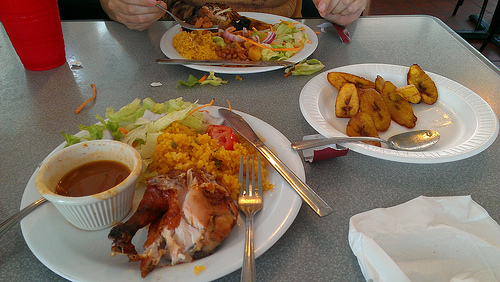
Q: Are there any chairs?
A: No, there are no chairs.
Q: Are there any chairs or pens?
A: No, there are no chairs or pens.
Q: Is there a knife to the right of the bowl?
A: Yes, there are knives to the right of the bowl.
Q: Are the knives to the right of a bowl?
A: Yes, the knives are to the right of a bowl.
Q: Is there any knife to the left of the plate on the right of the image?
A: Yes, there are knives to the left of the plate.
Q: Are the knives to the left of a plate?
A: Yes, the knives are to the left of a plate.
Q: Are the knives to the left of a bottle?
A: No, the knives are to the left of a plate.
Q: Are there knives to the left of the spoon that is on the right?
A: Yes, there are knives to the left of the spoon.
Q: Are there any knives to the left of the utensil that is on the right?
A: Yes, there are knives to the left of the spoon.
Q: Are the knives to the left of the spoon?
A: Yes, the knives are to the left of the spoon.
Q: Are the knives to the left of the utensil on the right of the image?
A: Yes, the knives are to the left of the spoon.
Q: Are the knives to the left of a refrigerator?
A: No, the knives are to the left of the spoon.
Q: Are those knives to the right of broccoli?
A: No, the knives are to the right of the lettuce.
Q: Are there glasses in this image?
A: No, there are no glasses.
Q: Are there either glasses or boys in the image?
A: No, there are no glasses or boys.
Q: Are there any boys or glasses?
A: No, there are no glasses or boys.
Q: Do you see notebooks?
A: No, there are no notebooks.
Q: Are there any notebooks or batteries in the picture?
A: No, there are no notebooks or batteries.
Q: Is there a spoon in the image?
A: Yes, there is a spoon.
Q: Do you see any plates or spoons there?
A: Yes, there is a spoon.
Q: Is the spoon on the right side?
A: Yes, the spoon is on the right of the image.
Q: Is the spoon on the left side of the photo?
A: No, the spoon is on the right of the image.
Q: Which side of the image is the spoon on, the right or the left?
A: The spoon is on the right of the image.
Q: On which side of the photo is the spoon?
A: The spoon is on the right of the image.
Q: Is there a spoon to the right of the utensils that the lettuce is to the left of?
A: Yes, there is a spoon to the right of the knives.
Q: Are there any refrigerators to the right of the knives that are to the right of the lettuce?
A: No, there is a spoon to the right of the knives.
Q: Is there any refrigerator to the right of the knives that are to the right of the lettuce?
A: No, there is a spoon to the right of the knives.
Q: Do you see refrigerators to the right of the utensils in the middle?
A: No, there is a spoon to the right of the knives.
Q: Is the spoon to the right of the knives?
A: Yes, the spoon is to the right of the knives.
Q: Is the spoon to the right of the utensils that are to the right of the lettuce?
A: Yes, the spoon is to the right of the knives.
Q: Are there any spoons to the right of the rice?
A: Yes, there is a spoon to the right of the rice.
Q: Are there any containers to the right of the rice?
A: No, there is a spoon to the right of the rice.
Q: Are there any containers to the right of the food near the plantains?
A: No, there is a spoon to the right of the rice.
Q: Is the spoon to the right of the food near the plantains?
A: Yes, the spoon is to the right of the rice.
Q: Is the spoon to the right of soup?
A: No, the spoon is to the right of the rice.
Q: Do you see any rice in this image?
A: Yes, there is rice.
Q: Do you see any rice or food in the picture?
A: Yes, there is rice.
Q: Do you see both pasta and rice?
A: No, there is rice but no pasta.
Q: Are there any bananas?
A: No, there are no bananas.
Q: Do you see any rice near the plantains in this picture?
A: Yes, there is rice near the plantains.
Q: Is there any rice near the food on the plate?
A: Yes, there is rice near the plantains.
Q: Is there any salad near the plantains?
A: No, there is rice near the plantains.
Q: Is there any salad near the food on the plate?
A: No, there is rice near the plantains.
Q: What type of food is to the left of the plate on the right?
A: The food is rice.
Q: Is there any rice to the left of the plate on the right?
A: Yes, there is rice to the left of the plate.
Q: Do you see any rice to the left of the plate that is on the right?
A: Yes, there is rice to the left of the plate.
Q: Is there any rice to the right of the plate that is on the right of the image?
A: No, the rice is to the left of the plate.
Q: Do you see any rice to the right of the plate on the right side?
A: No, the rice is to the left of the plate.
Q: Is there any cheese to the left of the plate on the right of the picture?
A: No, there is rice to the left of the plate.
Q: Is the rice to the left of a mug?
A: No, the rice is to the left of the plate.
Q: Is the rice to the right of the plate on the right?
A: No, the rice is to the left of the plate.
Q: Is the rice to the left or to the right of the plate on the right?
A: The rice is to the left of the plate.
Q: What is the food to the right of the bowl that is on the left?
A: The food is rice.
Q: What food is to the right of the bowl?
A: The food is rice.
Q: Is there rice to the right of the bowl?
A: Yes, there is rice to the right of the bowl.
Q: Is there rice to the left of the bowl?
A: No, the rice is to the right of the bowl.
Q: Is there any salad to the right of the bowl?
A: No, there is rice to the right of the bowl.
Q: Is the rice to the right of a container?
A: No, the rice is to the right of the bowl.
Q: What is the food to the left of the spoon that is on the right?
A: The food is rice.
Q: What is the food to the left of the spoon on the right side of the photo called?
A: The food is rice.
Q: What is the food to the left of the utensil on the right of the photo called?
A: The food is rice.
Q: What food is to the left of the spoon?
A: The food is rice.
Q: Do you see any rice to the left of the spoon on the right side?
A: Yes, there is rice to the left of the spoon.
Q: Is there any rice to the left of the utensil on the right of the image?
A: Yes, there is rice to the left of the spoon.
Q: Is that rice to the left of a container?
A: No, the rice is to the left of the spoon.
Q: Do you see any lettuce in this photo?
A: Yes, there is lettuce.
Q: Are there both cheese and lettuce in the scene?
A: No, there is lettuce but no cheese.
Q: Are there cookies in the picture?
A: No, there are no cookies.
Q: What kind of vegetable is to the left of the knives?
A: The vegetable is lettuce.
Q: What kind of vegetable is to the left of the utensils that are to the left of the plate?
A: The vegetable is lettuce.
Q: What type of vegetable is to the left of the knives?
A: The vegetable is lettuce.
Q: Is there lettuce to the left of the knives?
A: Yes, there is lettuce to the left of the knives.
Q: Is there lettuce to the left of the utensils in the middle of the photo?
A: Yes, there is lettuce to the left of the knives.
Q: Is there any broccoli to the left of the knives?
A: No, there is lettuce to the left of the knives.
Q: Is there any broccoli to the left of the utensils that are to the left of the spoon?
A: No, there is lettuce to the left of the knives.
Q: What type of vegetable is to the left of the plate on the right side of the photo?
A: The vegetable is lettuce.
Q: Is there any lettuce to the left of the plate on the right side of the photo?
A: Yes, there is lettuce to the left of the plate.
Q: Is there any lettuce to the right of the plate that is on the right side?
A: No, the lettuce is to the left of the plate.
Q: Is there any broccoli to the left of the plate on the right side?
A: No, there is lettuce to the left of the plate.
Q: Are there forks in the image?
A: Yes, there is a fork.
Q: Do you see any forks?
A: Yes, there is a fork.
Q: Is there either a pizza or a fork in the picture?
A: Yes, there is a fork.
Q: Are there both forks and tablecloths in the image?
A: No, there is a fork but no tablecloths.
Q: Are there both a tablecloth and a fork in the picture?
A: No, there is a fork but no tablecloths.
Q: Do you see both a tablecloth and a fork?
A: No, there is a fork but no tablecloths.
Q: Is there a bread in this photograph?
A: No, there is no breads.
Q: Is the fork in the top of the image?
A: Yes, the fork is in the top of the image.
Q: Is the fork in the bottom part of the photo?
A: No, the fork is in the top of the image.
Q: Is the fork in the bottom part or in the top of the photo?
A: The fork is in the top of the image.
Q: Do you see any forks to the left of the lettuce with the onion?
A: Yes, there is a fork to the left of the lettuce.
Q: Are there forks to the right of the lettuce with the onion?
A: No, the fork is to the left of the lettuce.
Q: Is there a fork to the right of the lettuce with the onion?
A: No, the fork is to the left of the lettuce.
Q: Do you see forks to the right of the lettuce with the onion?
A: No, the fork is to the left of the lettuce.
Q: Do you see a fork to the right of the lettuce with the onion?
A: No, the fork is to the left of the lettuce.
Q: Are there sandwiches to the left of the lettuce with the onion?
A: No, there is a fork to the left of the lettuce.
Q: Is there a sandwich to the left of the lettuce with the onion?
A: No, there is a fork to the left of the lettuce.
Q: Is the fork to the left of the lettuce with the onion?
A: Yes, the fork is to the left of the lettuce.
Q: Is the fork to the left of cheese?
A: No, the fork is to the left of the lettuce.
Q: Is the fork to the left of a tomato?
A: No, the fork is to the left of a carrot.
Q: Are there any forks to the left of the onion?
A: Yes, there is a fork to the left of the onion.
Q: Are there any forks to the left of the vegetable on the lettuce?
A: Yes, there is a fork to the left of the onion.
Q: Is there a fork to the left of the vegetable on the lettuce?
A: Yes, there is a fork to the left of the onion.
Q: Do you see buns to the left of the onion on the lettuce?
A: No, there is a fork to the left of the onion.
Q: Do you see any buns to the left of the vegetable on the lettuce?
A: No, there is a fork to the left of the onion.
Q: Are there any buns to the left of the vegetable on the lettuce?
A: No, there is a fork to the left of the onion.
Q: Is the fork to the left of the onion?
A: Yes, the fork is to the left of the onion.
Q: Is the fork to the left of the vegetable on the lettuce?
A: Yes, the fork is to the left of the onion.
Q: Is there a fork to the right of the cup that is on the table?
A: Yes, there is a fork to the right of the cup.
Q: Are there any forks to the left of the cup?
A: No, the fork is to the right of the cup.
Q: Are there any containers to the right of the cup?
A: No, there is a fork to the right of the cup.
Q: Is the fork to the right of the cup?
A: Yes, the fork is to the right of the cup.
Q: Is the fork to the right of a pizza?
A: No, the fork is to the right of the cup.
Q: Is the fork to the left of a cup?
A: No, the fork is to the right of a cup.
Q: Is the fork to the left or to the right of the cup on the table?
A: The fork is to the right of the cup.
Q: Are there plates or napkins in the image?
A: Yes, there is a plate.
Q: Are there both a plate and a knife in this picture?
A: Yes, there are both a plate and a knife.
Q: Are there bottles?
A: No, there are no bottles.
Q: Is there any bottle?
A: No, there are no bottles.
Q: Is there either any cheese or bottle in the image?
A: No, there are no bottles or cheese.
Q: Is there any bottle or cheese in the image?
A: No, there are no bottles or cheese.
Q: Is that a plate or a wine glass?
A: That is a plate.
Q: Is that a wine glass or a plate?
A: That is a plate.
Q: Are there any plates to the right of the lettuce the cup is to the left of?
A: Yes, there is a plate to the right of the lettuce.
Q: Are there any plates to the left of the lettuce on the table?
A: No, the plate is to the right of the lettuce.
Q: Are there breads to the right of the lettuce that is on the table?
A: No, there is a plate to the right of the lettuce.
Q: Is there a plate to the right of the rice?
A: Yes, there is a plate to the right of the rice.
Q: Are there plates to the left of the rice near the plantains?
A: No, the plate is to the right of the rice.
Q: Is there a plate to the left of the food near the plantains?
A: No, the plate is to the right of the rice.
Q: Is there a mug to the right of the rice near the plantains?
A: No, there is a plate to the right of the rice.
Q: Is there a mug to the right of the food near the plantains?
A: No, there is a plate to the right of the rice.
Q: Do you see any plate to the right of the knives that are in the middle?
A: Yes, there is a plate to the right of the knives.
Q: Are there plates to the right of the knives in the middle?
A: Yes, there is a plate to the right of the knives.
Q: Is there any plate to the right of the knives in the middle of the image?
A: Yes, there is a plate to the right of the knives.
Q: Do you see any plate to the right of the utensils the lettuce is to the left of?
A: Yes, there is a plate to the right of the knives.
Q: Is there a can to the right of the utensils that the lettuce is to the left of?
A: No, there is a plate to the right of the knives.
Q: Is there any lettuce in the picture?
A: Yes, there is lettuce.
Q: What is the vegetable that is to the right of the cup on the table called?
A: The vegetable is lettuce.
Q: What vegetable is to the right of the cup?
A: The vegetable is lettuce.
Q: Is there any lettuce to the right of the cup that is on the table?
A: Yes, there is lettuce to the right of the cup.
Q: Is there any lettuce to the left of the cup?
A: No, the lettuce is to the right of the cup.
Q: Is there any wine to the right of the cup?
A: No, there is lettuce to the right of the cup.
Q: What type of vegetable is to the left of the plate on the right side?
A: The vegetable is lettuce.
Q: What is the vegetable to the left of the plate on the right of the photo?
A: The vegetable is lettuce.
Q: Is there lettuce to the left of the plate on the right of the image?
A: Yes, there is lettuce to the left of the plate.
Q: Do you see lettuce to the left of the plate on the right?
A: Yes, there is lettuce to the left of the plate.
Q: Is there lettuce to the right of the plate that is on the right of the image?
A: No, the lettuce is to the left of the plate.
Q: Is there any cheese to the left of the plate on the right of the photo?
A: No, there is lettuce to the left of the plate.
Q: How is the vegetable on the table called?
A: The vegetable is lettuce.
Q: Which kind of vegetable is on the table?
A: The vegetable is lettuce.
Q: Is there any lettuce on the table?
A: Yes, there is lettuce on the table.